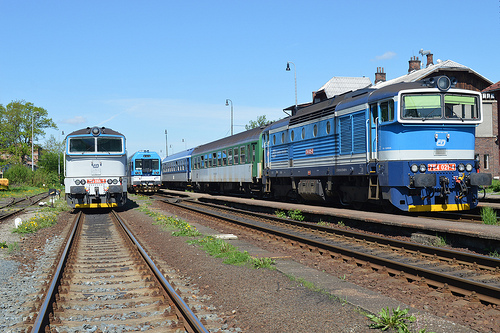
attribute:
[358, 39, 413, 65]
clouds — are white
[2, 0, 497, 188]
sky — is blue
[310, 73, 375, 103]
roof — white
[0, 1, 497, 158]
sky — blue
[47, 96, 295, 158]
clouds — white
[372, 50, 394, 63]
clouds — white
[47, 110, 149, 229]
train — is grey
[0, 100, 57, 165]
tree — in distance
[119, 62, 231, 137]
clouds — white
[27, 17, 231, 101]
sky — blue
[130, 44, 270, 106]
sky — blue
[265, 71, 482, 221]
train engine — white, blue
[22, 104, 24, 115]
leaves — are green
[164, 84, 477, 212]
train — is blue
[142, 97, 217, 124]
cloud — is white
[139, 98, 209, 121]
cloud — is white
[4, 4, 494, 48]
sky — is blue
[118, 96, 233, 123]
cloud — white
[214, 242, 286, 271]
grass — patch